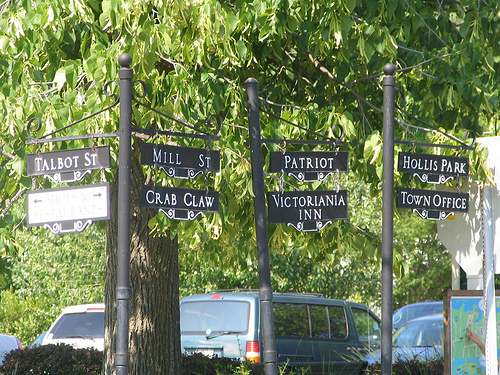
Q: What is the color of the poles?
A: Black.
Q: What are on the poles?
A: Signs.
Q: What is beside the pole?
A: A tree.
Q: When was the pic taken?
A: During the day.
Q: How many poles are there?
A: 3.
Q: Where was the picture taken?
A: On the sidewalk.